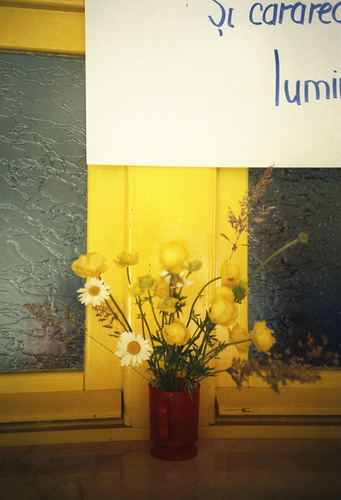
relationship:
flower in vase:
[157, 323, 189, 349] [147, 383, 198, 455]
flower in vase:
[201, 295, 241, 330] [147, 383, 198, 455]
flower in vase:
[243, 313, 279, 349] [147, 383, 198, 455]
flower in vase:
[159, 243, 190, 271] [147, 383, 198, 455]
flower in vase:
[69, 253, 108, 279] [147, 383, 198, 455]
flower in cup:
[117, 329, 152, 371] [145, 373, 202, 462]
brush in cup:
[23, 163, 339, 388] [145, 373, 202, 462]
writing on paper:
[207, 1, 340, 109] [84, 0, 340, 167]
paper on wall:
[84, 0, 340, 167] [1, 0, 339, 446]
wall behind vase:
[128, 169, 223, 230] [132, 363, 209, 472]